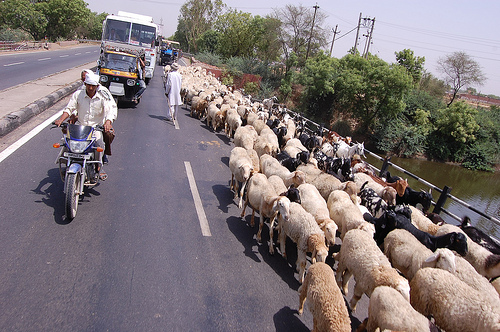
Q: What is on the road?
A: Sheep.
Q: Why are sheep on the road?
A: Being relocated.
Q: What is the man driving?
A: Motorcycle.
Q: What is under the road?
A: River.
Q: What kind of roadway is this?
A: Highway.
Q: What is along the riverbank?
A: Trees.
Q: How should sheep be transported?
A: Truck.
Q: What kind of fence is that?
A: Wooden.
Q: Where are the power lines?
A: Far right of scene.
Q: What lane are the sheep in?
A: Left lane.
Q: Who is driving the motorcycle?
A: Man in white hat.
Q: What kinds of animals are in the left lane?
A: Sheep and goats.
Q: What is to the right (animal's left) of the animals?
A: Railing.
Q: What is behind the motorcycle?
A: Small vehicle.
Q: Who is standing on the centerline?
A: Man in white clothing.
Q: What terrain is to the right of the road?
A: Water and shoreline.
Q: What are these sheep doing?
A: Moving down the road.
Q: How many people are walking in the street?
A: One person.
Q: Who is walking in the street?
A: A shepherd.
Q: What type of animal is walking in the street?
A: Sheep.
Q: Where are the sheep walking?
A: On a bridge.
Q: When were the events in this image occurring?
A: During the day.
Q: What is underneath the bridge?
A: A river.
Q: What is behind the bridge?
A: Trees.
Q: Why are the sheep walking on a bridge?
A: To get to the other side.